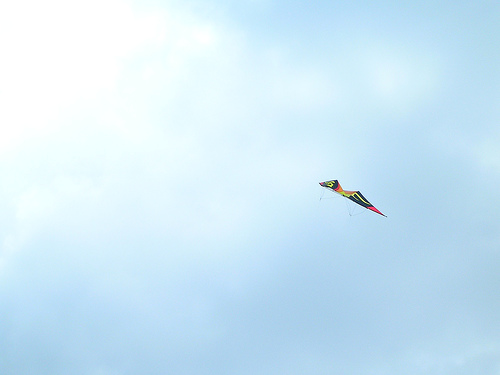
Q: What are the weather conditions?
A: It is cloudy.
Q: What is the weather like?
A: It is cloudy.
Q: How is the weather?
A: It is cloudy.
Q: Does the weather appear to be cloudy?
A: Yes, it is cloudy.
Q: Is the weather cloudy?
A: Yes, it is cloudy.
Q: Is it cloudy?
A: Yes, it is cloudy.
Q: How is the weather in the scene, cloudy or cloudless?
A: It is cloudy.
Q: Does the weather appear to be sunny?
A: No, it is cloudy.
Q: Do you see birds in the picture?
A: No, there are no birds.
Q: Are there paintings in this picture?
A: No, there are no paintings.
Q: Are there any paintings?
A: No, there are no paintings.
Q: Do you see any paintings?
A: No, there are no paintings.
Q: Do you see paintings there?
A: No, there are no paintings.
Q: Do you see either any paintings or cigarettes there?
A: No, there are no paintings or cigarettes.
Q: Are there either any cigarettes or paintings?
A: No, there are no paintings or cigarettes.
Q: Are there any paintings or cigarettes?
A: No, there are no paintings or cigarettes.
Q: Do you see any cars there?
A: No, there are no cars.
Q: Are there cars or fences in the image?
A: No, there are no cars or fences.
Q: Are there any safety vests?
A: No, there are no safety vests.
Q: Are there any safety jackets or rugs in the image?
A: No, there are no safety jackets or rugs.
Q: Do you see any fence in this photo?
A: No, there are no fences.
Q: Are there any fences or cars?
A: No, there are no fences or cars.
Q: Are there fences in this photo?
A: No, there are no fences.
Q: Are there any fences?
A: No, there are no fences.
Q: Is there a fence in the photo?
A: No, there are no fences.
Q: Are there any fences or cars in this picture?
A: No, there are no fences or cars.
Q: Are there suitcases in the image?
A: No, there are no suitcases.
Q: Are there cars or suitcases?
A: No, there are no suitcases or cars.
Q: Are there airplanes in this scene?
A: Yes, there is an airplane.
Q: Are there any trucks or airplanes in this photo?
A: Yes, there is an airplane.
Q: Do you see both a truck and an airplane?
A: No, there is an airplane but no trucks.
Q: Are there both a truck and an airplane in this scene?
A: No, there is an airplane but no trucks.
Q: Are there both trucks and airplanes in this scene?
A: No, there is an airplane but no trucks.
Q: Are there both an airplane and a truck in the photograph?
A: No, there is an airplane but no trucks.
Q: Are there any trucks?
A: No, there are no trucks.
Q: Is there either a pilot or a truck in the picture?
A: No, there are no trucks or pilots.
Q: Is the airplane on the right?
A: Yes, the airplane is on the right of the image.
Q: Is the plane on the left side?
A: No, the plane is on the right of the image.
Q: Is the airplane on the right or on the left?
A: The airplane is on the right of the image.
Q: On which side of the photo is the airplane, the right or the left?
A: The airplane is on the right of the image.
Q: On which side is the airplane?
A: The airplane is on the right of the image.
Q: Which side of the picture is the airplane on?
A: The airplane is on the right of the image.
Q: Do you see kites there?
A: Yes, there is a kite.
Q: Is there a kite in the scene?
A: Yes, there is a kite.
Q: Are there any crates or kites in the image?
A: Yes, there is a kite.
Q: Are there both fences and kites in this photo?
A: No, there is a kite but no fences.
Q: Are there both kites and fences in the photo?
A: No, there is a kite but no fences.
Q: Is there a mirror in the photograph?
A: No, there are no mirrors.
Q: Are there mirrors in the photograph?
A: No, there are no mirrors.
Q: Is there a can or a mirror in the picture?
A: No, there are no mirrors or cans.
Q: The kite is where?
A: The kite is in the sky.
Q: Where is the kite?
A: The kite is in the sky.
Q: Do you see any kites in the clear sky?
A: Yes, there is a kite in the sky.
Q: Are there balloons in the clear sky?
A: No, there is a kite in the sky.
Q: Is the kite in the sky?
A: Yes, the kite is in the sky.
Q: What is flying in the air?
A: The kite is flying in the air.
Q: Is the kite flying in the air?
A: Yes, the kite is flying in the air.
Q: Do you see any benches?
A: No, there are no benches.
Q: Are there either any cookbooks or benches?
A: No, there are no benches or cookbooks.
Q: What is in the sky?
A: The clouds are in the sky.